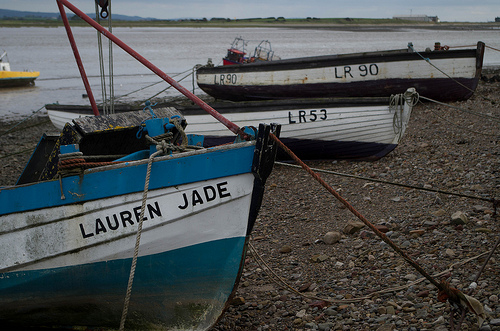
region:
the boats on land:
[1, 36, 484, 329]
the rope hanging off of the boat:
[84, 115, 195, 327]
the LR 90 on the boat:
[332, 63, 377, 79]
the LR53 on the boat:
[287, 109, 328, 124]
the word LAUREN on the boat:
[77, 202, 162, 238]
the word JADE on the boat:
[177, 180, 229, 209]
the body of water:
[0, 25, 499, 120]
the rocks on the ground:
[0, 68, 499, 328]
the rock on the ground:
[321, 229, 343, 243]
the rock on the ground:
[341, 219, 366, 235]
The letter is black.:
[327, 63, 344, 80]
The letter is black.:
[339, 63, 355, 81]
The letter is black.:
[283, 109, 297, 126]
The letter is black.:
[296, 107, 310, 124]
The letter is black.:
[174, 189, 189, 211]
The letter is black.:
[188, 188, 204, 210]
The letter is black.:
[201, 180, 219, 202]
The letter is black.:
[215, 177, 233, 199]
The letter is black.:
[146, 198, 163, 223]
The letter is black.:
[71, 220, 96, 240]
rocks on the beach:
[320, 265, 345, 286]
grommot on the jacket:
[396, 292, 441, 317]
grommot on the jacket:
[417, 239, 427, 254]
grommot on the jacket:
[277, 301, 298, 318]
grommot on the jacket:
[390, 216, 398, 228]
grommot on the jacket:
[258, 305, 285, 325]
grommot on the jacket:
[313, 260, 333, 280]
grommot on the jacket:
[403, 302, 418, 313]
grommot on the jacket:
[300, 215, 320, 236]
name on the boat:
[75, 189, 240, 228]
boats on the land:
[46, 20, 486, 304]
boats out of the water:
[22, 16, 450, 329]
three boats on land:
[39, 12, 497, 251]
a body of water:
[11, 8, 250, 98]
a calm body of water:
[12, 2, 239, 107]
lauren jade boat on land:
[48, 163, 305, 283]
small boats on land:
[187, 33, 497, 223]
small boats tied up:
[82, 43, 497, 293]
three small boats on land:
[7, 23, 496, 273]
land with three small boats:
[15, 1, 465, 316]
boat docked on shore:
[192, 32, 492, 99]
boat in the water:
[1, 45, 40, 84]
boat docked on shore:
[48, 93, 444, 145]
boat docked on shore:
[3, 68, 333, 330]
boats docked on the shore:
[1, 26, 486, 325]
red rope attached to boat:
[269, 119, 492, 329]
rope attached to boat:
[401, 90, 497, 127]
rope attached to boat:
[474, 36, 499, 56]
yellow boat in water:
[0, 50, 38, 85]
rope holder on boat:
[131, 115, 201, 151]